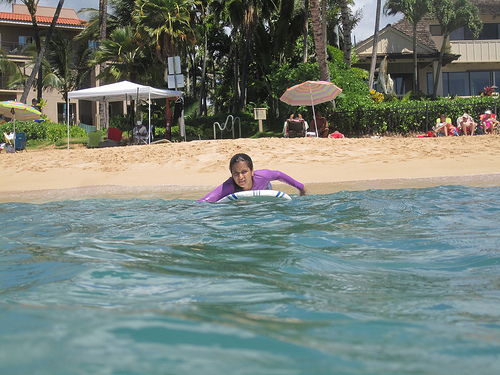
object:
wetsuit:
[197, 168, 304, 203]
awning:
[68, 81, 184, 104]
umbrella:
[1, 100, 42, 153]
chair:
[287, 119, 306, 138]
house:
[346, 1, 497, 105]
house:
[0, 3, 126, 128]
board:
[216, 189, 294, 203]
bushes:
[341, 95, 494, 132]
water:
[0, 187, 500, 375]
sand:
[1, 147, 147, 182]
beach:
[0, 134, 499, 203]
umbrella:
[280, 80, 342, 139]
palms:
[22, 19, 111, 127]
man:
[132, 120, 148, 144]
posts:
[67, 80, 185, 149]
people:
[436, 114, 450, 137]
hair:
[230, 153, 253, 173]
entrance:
[368, 64, 430, 98]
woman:
[198, 153, 307, 203]